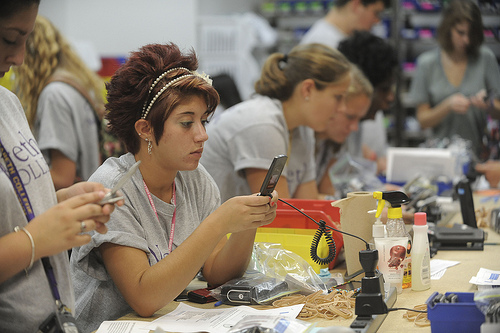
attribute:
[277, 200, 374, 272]
cord — long, black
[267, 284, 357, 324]
rubber bands — in pile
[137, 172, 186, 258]
lanyard — pink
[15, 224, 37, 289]
bracelet — silver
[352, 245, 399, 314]
stamp — black, large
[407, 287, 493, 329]
container — blue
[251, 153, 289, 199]
phone — charger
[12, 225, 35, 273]
bracelet — silver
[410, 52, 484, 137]
shirt — gray